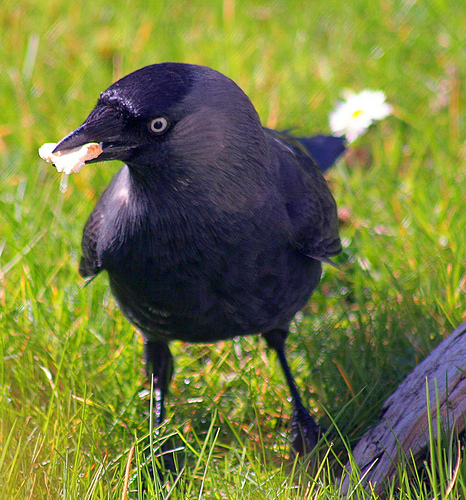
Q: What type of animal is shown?
A: Bird.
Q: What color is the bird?
A: Black.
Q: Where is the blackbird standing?
A: In grass.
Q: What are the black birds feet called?
A: Claws.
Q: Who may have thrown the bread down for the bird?
A: Bird watcher.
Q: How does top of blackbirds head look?
A: Shiny.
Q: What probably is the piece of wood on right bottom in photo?
A: Dead branch.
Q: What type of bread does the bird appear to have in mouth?
A: White.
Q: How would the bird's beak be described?
A: As black.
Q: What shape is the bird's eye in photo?
A: Round.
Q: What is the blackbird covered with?
A: Feathers.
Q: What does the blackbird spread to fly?
A: Wings.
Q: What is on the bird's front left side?
A: Broken piece of wood.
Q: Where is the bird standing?
A: In green grass.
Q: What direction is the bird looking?
A: Camera left.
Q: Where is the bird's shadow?
A: In the grass.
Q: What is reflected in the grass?
A: Sunlight.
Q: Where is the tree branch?
A: Next to the bird.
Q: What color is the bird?
A: Black.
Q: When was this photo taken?
A: Daytime.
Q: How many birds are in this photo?
A: One.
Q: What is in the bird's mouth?
A: A piece of popcorn.